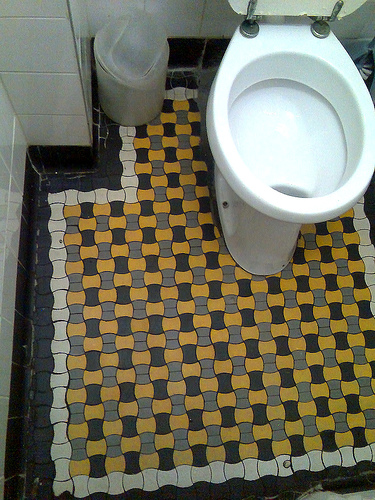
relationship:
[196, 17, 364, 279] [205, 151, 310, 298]
toilet has base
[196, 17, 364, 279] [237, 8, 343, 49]
toilet has metal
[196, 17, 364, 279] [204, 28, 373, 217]
toilet has seat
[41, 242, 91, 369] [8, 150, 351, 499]
tiles on floor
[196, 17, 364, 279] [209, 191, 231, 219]
toilet has bolt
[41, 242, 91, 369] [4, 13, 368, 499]
tiles in bathroom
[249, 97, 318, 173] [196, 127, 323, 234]
water in bowl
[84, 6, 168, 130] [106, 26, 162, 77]
trash can has lid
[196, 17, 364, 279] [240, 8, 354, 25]
toilet has hinges